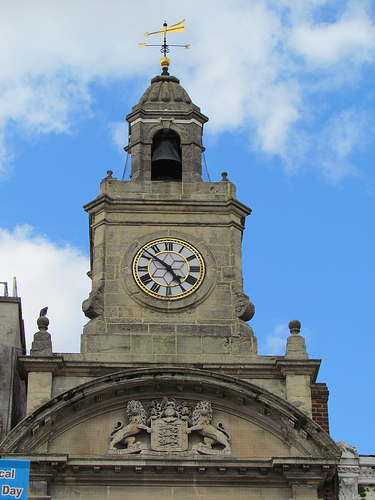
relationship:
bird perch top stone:
[39, 306, 48, 317] [37, 315, 48, 329]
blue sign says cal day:
[0, 458, 32, 499] [1, 466, 24, 495]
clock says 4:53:
[121, 230, 217, 313] [136, 240, 186, 291]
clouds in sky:
[231, 32, 352, 186] [276, 200, 336, 270]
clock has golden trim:
[121, 230, 217, 313] [131, 235, 207, 301]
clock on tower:
[121, 233, 221, 313] [5, 69, 313, 498]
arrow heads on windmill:
[137, 30, 149, 47] [138, 17, 190, 70]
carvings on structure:
[108, 400, 155, 455] [6, 363, 338, 453]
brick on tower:
[314, 383, 326, 430] [79, 25, 257, 351]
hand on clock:
[166, 265, 181, 284] [121, 230, 217, 313]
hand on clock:
[166, 265, 181, 284] [115, 221, 218, 312]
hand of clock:
[142, 248, 172, 271] [133, 233, 210, 307]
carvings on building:
[108, 400, 155, 455] [4, 17, 363, 496]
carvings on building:
[183, 400, 232, 457] [4, 17, 363, 496]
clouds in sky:
[0, 0, 375, 353] [3, 3, 373, 351]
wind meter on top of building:
[137, 19, 189, 69] [4, 17, 363, 496]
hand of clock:
[170, 271, 182, 292] [121, 230, 217, 313]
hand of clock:
[141, 242, 173, 264] [121, 230, 217, 313]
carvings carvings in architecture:
[108, 400, 155, 455] [0, 19, 345, 493]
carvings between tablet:
[183, 400, 232, 457] [146, 396, 191, 454]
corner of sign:
[1, 458, 36, 499] [2, 458, 29, 494]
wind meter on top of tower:
[138, 19, 191, 70] [79, 13, 299, 487]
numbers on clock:
[137, 241, 201, 299] [121, 237, 209, 300]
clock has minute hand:
[121, 230, 217, 313] [142, 246, 170, 272]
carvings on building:
[183, 400, 232, 457] [15, 154, 315, 481]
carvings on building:
[108, 400, 155, 455] [15, 154, 315, 481]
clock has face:
[121, 230, 217, 313] [132, 237, 200, 297]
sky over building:
[3, 29, 363, 447] [4, 17, 363, 496]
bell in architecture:
[146, 135, 186, 172] [0, 19, 375, 500]